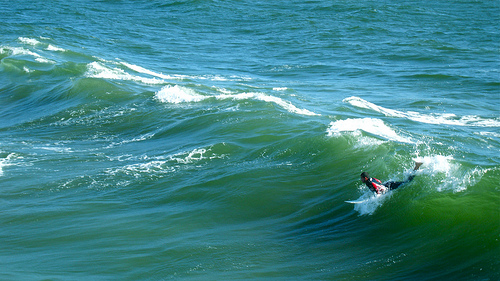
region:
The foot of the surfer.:
[411, 160, 423, 165]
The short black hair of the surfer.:
[360, 172, 367, 177]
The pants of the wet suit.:
[388, 176, 411, 187]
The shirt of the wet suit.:
[370, 179, 381, 191]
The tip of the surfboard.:
[346, 198, 352, 203]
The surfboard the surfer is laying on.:
[340, 190, 395, 202]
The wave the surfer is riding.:
[282, 124, 489, 251]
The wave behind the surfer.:
[345, 82, 490, 139]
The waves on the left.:
[9, 38, 277, 170]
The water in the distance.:
[117, 8, 494, 88]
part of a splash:
[356, 205, 368, 229]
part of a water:
[251, 198, 284, 237]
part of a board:
[335, 179, 362, 215]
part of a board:
[321, 164, 371, 225]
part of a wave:
[241, 145, 276, 175]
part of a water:
[234, 199, 282, 256]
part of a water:
[333, 180, 371, 220]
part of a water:
[212, 205, 246, 257]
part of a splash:
[363, 200, 375, 215]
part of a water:
[216, 178, 248, 238]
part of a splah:
[353, 188, 375, 215]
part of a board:
[353, 187, 366, 202]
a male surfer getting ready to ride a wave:
[347, 130, 437, 231]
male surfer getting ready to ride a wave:
[177, 62, 480, 257]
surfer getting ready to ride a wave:
[222, 48, 477, 255]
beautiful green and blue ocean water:
[27, 20, 313, 257]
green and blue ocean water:
[32, 8, 284, 203]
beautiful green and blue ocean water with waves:
[27, 32, 280, 231]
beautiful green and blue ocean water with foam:
[118, 56, 286, 138]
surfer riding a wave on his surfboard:
[7, 38, 470, 259]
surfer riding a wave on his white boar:
[272, 88, 469, 265]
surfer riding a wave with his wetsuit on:
[34, 25, 464, 238]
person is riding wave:
[323, 147, 424, 197]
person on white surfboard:
[320, 162, 420, 202]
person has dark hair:
[350, 165, 380, 205]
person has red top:
[355, 156, 377, 201]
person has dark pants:
[380, 171, 425, 197]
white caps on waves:
[115, 62, 395, 158]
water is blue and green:
[125, 161, 375, 276]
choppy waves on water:
[192, 20, 412, 136]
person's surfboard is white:
[341, 186, 374, 222]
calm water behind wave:
[172, 7, 402, 59]